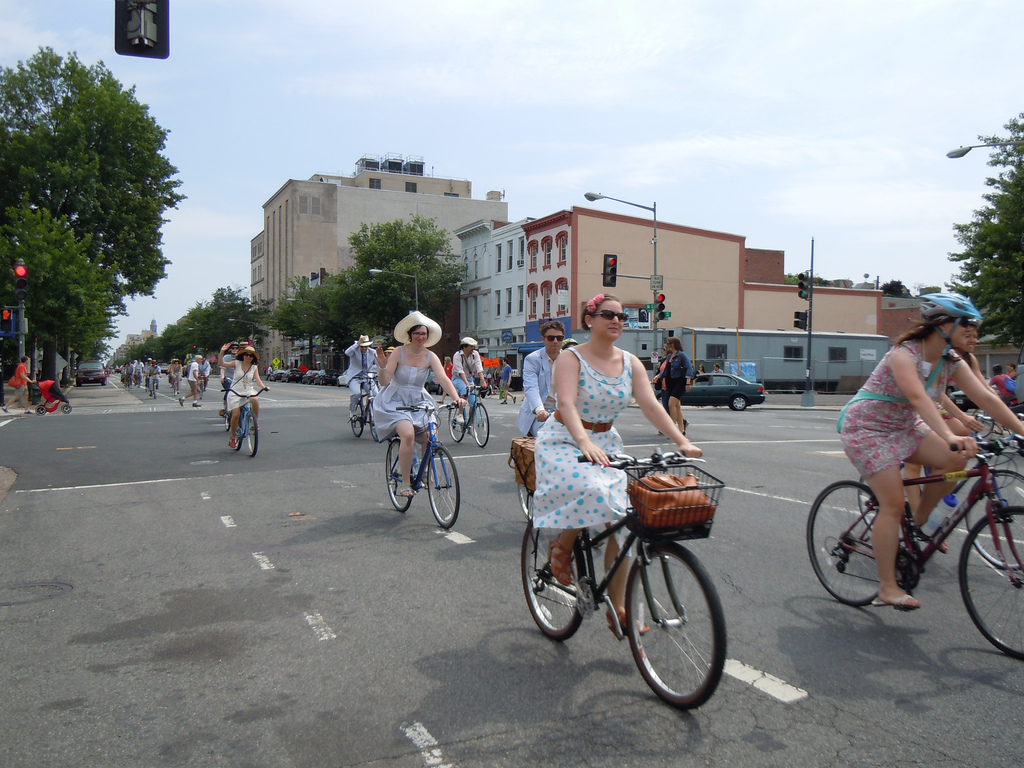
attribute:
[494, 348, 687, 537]
sundress — white, blue, floral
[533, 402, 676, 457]
belt — brown, leather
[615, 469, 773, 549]
bag — leather, brown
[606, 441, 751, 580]
purse — brown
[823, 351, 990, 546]
dress — pink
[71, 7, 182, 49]
light — red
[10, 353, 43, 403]
woman — pushing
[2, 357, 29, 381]
shirt — red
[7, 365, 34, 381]
shirt — red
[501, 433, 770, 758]
bike — black, metal